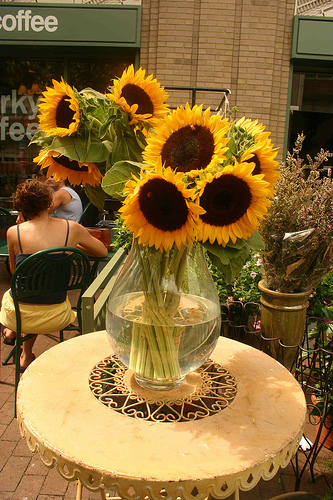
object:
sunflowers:
[27, 59, 283, 256]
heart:
[151, 401, 182, 422]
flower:
[118, 154, 207, 254]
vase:
[105, 233, 221, 392]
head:
[11, 174, 53, 219]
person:
[0, 177, 109, 373]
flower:
[257, 129, 333, 294]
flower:
[193, 155, 272, 249]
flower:
[141, 99, 232, 184]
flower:
[31, 148, 103, 189]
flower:
[238, 137, 281, 196]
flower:
[36, 75, 81, 140]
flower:
[226, 295, 234, 307]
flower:
[239, 297, 243, 302]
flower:
[231, 283, 236, 292]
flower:
[255, 257, 264, 266]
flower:
[253, 253, 260, 259]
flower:
[253, 320, 262, 330]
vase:
[257, 279, 313, 374]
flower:
[107, 63, 170, 128]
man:
[45, 173, 83, 224]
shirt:
[52, 185, 82, 222]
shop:
[0, 0, 142, 210]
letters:
[0, 7, 59, 34]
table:
[16, 328, 306, 499]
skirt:
[0, 286, 78, 335]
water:
[107, 290, 222, 380]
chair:
[1, 245, 111, 418]